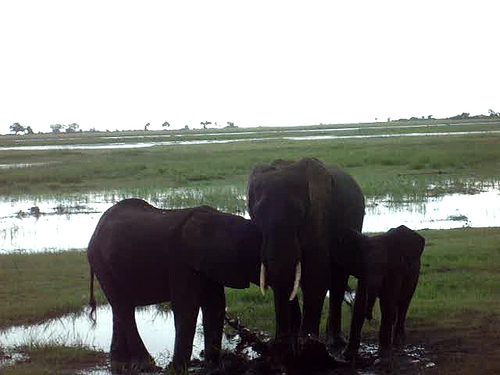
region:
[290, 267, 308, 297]
the elephants tusk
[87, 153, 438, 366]
three elephants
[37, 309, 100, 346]
a small area of water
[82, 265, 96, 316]
the tail of the elephant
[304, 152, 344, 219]
the elephants ear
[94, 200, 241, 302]
a grey elephant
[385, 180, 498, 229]
an area of water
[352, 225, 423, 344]
a small elephant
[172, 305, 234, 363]
front legs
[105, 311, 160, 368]
back legs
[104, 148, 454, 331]
three different elephants in the photo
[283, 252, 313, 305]
white tusk on the animal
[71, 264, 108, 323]
tail of the animal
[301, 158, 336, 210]
ear of the elephant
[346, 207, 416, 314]
small elephant in the photo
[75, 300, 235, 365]
legs of the elephant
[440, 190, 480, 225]
water behind the elephant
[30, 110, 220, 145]
trees in the distance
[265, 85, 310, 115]
sky above the trees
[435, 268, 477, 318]
grass under the elephant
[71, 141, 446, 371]
Three elephants at a safari.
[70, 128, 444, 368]
One adult elephant with her two children.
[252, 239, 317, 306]
Tusks protruding from an elephant.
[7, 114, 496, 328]
Savannah area with watery areas.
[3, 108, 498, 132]
Line of trees alongside a savanna area.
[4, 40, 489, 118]
Clear sky during early morning.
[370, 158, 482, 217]
Patches of grass within an watery area.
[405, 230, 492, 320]
Low level grass within a wetland savanna area.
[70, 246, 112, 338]
Long tail of a baby elephant.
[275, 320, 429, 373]
Muddy area where elephants are standing.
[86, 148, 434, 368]
three elephants standing together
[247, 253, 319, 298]
white tusks of middle elephant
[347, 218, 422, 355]
smallest elephant of group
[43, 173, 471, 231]
grass growing in water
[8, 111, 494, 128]
trees dotting the horizon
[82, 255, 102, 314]
tail of elephant on the left side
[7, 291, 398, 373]
puddle of water elephants are standing in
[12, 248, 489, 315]
strip of grass between two water puddles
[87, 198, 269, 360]
elephant nuzzling middle elephant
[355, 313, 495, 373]
dirt patch next to water puddle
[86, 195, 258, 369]
a small grey elephant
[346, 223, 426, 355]
a small grey elephant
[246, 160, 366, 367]
a large grey elephant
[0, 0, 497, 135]
a hazy white sky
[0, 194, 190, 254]
a large puddle of water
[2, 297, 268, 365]
a large puddle of water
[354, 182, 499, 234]
a large puddle of water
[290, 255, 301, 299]
a white elephant tusk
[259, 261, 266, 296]
a white elephant tusk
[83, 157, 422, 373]
a pride of elephants